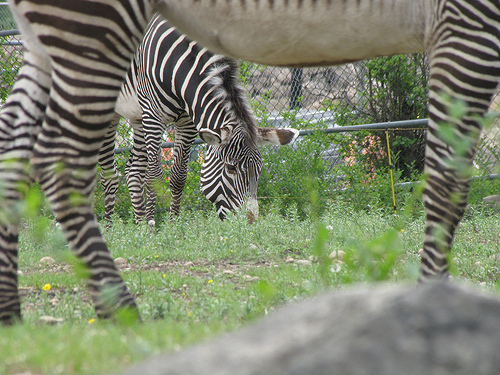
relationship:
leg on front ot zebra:
[404, 8, 474, 291] [80, 3, 499, 160]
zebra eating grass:
[155, 46, 266, 206] [182, 221, 315, 279]